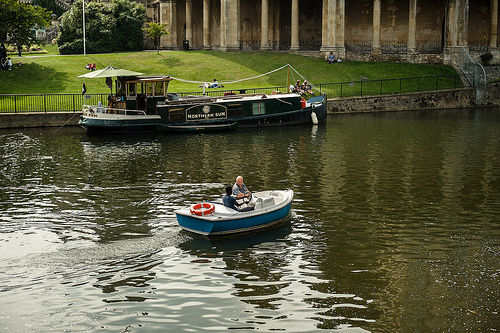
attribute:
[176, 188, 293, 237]
boat — for tours, small, white, blue, short, aqua blue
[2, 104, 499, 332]
river — a small body, green, here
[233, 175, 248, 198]
tourist — sitting, white, older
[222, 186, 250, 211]
passenger — driving, black, younger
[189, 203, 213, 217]
lifesaver — a life saver, orange, for floatation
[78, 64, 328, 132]
boat — for tours, black, flat, long, anchored, large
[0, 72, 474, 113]
fencing — for safety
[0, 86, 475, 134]
wall — low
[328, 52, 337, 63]
person — here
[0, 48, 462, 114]
grass — sloped, tall, green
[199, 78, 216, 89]
person — here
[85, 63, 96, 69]
person — lounging, here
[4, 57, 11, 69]
person — here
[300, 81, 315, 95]
person — lounging, here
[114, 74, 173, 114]
cabin — in front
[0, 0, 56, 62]
trees — here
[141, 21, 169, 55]
trees — here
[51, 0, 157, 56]
trees — here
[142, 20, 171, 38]
leaves — green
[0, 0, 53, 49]
leaves — green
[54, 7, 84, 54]
leaves — green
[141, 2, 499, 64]
ruin — historic, old, here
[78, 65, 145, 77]
umbrella — green, square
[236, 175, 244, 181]
hair — white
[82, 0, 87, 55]
flag pole — on the hill